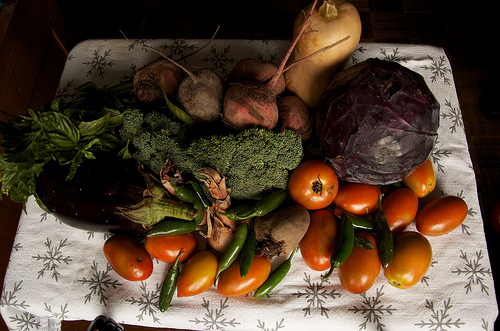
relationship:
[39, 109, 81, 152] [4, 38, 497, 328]
basil on cloth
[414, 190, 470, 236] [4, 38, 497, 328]
tomatoe on cloth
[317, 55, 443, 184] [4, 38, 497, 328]
cabbage on cloth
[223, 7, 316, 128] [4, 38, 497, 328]
beet on cloth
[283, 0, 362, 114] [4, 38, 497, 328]
gourd on cloth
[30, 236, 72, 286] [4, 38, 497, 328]
snowflake on cloth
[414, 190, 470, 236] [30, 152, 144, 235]
tomatoe on bowl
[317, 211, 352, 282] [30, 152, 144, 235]
pepper on bowl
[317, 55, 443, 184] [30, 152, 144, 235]
cabbage on bowl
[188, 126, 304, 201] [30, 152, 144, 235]
broccoli on bowl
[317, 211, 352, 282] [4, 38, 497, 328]
pepper on cloth